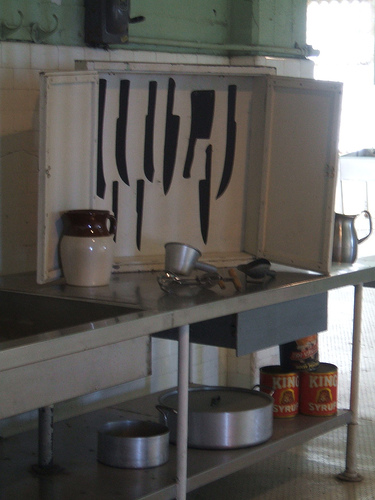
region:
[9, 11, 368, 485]
kitchen table with containers and knives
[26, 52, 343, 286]
open white storage case with black knives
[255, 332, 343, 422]
colorful canned goods neatly stacked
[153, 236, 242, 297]
metal beaters in front of metal measuring cup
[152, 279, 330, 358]
gray drawer under metal counter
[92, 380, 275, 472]
open pan next to lidded pot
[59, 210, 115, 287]
the brown and white pitcher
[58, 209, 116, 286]
the dark brown area on the pitcher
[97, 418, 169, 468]
the small metal pot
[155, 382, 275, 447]
the large metal pot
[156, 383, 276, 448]
the handles on the pot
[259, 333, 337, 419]
the large cans that are stacked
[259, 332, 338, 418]
the labels on the cans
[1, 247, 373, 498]
the countertop made of metal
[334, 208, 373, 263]
the pitcher made of metal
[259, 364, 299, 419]
the word KING on the label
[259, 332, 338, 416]
the cans are large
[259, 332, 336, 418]
the cans are stacked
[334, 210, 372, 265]
the metal pitcher has a spout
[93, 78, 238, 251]
the black shapes of knives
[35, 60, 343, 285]
the opened white cabinet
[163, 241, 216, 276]
the large metal measuring cup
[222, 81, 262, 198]
a knife in a cabinet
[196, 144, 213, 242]
a knife in a cabinet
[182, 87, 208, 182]
a knife in a cabinet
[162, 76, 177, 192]
a knife in a cabinet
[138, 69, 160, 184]
a knife in a cabinet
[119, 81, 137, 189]
a knife in a cabinet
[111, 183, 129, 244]
a knife in a cabinet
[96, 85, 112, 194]
a knife in a cabinet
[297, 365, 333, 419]
a can on a shelf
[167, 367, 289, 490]
a pot on a shelf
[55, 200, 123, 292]
Jar on the counter is brown and tan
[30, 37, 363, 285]
Box has places for different types of knives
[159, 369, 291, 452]
Large sauce pan is under the steel table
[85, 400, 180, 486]
Stock pot is on the lower shelf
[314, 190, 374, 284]
Silver pitcher is on the corner of the table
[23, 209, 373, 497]
Large table is in the kitchen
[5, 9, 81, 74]
Hooks are attached to the wall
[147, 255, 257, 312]
Hand mixer is on the steel counter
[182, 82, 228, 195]
a silhouette of a meat cleaver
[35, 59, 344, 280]
white box holding the knives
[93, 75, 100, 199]
knife on the left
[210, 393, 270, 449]
large stainless steel pot sitting on the bottom shelf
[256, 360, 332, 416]
large copper pot sitting on the bottom shelf